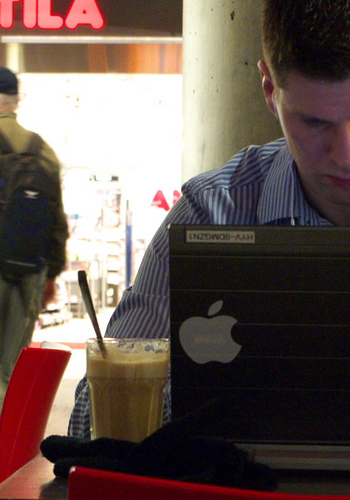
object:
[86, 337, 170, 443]
glass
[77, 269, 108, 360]
spoon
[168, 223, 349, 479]
laptop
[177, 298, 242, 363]
apple logo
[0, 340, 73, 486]
chair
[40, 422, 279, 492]
gloves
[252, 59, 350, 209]
half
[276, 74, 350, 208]
face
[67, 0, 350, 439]
person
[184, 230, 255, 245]
label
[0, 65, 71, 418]
person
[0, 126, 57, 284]
backpack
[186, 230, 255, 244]
serial number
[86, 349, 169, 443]
coffee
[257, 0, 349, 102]
hair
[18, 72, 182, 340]
entrance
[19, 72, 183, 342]
store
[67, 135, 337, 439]
shirt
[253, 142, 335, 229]
collar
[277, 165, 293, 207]
stripes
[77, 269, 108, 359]
handle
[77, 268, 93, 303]
part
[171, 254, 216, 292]
part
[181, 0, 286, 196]
pole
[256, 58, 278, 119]
ear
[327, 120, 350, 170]
nose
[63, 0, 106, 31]
letter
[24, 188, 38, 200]
lettering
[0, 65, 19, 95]
cap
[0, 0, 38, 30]
letters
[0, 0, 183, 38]
sign